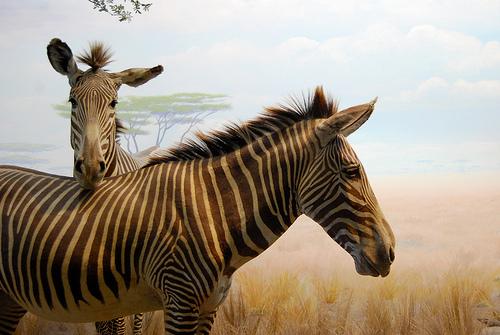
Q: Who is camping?
A: No one.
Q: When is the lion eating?
A: No lion.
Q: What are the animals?
A: Zebras.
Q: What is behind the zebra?
A: A tree.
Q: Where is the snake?
A: No snake.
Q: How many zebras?
A: Two.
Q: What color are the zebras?
A: Black and white.